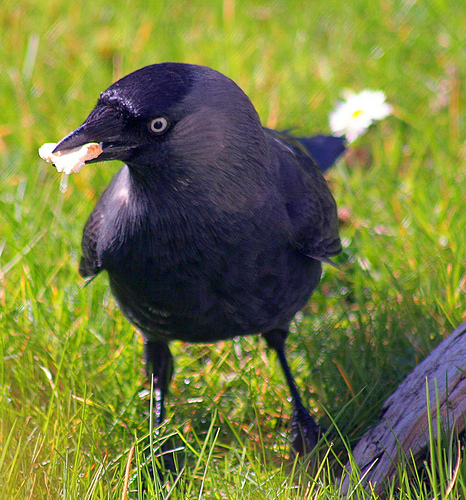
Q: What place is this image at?
A: It is at the field.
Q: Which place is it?
A: It is a field.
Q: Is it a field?
A: Yes, it is a field.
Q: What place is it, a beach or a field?
A: It is a field.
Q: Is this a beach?
A: No, it is a field.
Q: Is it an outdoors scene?
A: Yes, it is outdoors.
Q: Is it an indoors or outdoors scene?
A: It is outdoors.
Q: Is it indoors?
A: No, it is outdoors.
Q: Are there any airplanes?
A: No, there are no airplanes.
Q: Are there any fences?
A: No, there are no fences.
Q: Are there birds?
A: Yes, there is a bird.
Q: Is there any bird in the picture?
A: Yes, there is a bird.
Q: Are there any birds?
A: Yes, there is a bird.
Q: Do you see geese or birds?
A: Yes, there is a bird.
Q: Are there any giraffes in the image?
A: No, there are no giraffes.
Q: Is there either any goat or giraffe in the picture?
A: No, there are no giraffes or goats.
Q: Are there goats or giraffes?
A: No, there are no giraffes or goats.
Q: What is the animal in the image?
A: The animal is a bird.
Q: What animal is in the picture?
A: The animal is a bird.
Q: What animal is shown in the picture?
A: The animal is a bird.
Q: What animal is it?
A: The animal is a bird.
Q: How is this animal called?
A: That is a bird.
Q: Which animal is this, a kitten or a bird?
A: That is a bird.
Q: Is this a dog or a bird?
A: This is a bird.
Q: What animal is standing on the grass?
A: The bird is standing on the grass.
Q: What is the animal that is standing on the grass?
A: The animal is a bird.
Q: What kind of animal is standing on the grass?
A: The animal is a bird.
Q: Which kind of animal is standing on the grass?
A: The animal is a bird.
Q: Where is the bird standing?
A: The bird is standing on the grass.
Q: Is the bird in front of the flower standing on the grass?
A: Yes, the bird is standing on the grass.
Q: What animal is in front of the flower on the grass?
A: The bird is in front of the flower.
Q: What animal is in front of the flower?
A: The bird is in front of the flower.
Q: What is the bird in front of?
A: The bird is in front of the flower.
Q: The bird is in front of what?
A: The bird is in front of the flower.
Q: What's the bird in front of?
A: The bird is in front of the flower.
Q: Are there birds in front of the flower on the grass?
A: Yes, there is a bird in front of the flower.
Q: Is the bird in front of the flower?
A: Yes, the bird is in front of the flower.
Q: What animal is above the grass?
A: The animal is a bird.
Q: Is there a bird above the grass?
A: Yes, there is a bird above the grass.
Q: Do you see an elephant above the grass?
A: No, there is a bird above the grass.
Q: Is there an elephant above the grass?
A: No, there is a bird above the grass.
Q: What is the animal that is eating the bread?
A: The animal is a bird.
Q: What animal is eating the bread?
A: The animal is a bird.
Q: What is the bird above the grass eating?
A: The bird is eating a bread.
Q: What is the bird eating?
A: The bird is eating a bread.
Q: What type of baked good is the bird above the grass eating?
A: The bird is eating a bread.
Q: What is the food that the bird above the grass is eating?
A: The food is a bread.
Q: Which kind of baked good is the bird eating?
A: The bird is eating a bread.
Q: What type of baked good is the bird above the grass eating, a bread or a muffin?
A: The bird is eating a bread.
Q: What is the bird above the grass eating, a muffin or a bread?
A: The bird is eating a bread.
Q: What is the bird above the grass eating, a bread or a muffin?
A: The bird is eating a bread.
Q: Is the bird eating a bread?
A: Yes, the bird is eating a bread.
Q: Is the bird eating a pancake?
A: No, the bird is eating a bread.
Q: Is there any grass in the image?
A: Yes, there is grass.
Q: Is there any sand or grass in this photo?
A: Yes, there is grass.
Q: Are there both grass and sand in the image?
A: No, there is grass but no sand.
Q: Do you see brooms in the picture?
A: No, there are no brooms.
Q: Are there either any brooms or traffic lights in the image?
A: No, there are no brooms or traffic lights.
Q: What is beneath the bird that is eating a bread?
A: The grass is beneath the bird.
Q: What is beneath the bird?
A: The grass is beneath the bird.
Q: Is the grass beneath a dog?
A: No, the grass is beneath the bird.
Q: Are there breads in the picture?
A: Yes, there is a bread.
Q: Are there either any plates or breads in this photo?
A: Yes, there is a bread.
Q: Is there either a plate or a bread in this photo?
A: Yes, there is a bread.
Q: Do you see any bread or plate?
A: Yes, there is a bread.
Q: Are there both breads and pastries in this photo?
A: No, there is a bread but no pastries.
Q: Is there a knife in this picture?
A: No, there are no knives.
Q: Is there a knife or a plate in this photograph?
A: No, there are no knives or plates.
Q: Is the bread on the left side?
A: Yes, the bread is on the left of the image.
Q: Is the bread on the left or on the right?
A: The bread is on the left of the image.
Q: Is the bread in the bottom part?
A: No, the bread is in the top of the image.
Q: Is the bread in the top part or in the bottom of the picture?
A: The bread is in the top of the image.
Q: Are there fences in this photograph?
A: No, there are no fences.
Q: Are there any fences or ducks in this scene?
A: No, there are no fences or ducks.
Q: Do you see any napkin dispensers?
A: No, there are no napkin dispensers.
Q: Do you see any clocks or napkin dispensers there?
A: No, there are no napkin dispensers or clocks.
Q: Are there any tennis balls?
A: No, there are no tennis balls.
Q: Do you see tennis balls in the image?
A: No, there are no tennis balls.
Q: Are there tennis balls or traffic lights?
A: No, there are no tennis balls or traffic lights.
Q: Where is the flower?
A: The flower is on the grass.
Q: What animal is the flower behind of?
A: The flower is behind the bird.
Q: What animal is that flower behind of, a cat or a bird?
A: The flower is behind a bird.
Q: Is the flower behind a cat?
A: No, the flower is behind the bird.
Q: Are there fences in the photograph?
A: No, there are no fences.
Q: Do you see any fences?
A: No, there are no fences.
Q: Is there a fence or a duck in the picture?
A: No, there are no fences or ducks.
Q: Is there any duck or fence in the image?
A: No, there are no fences or ducks.